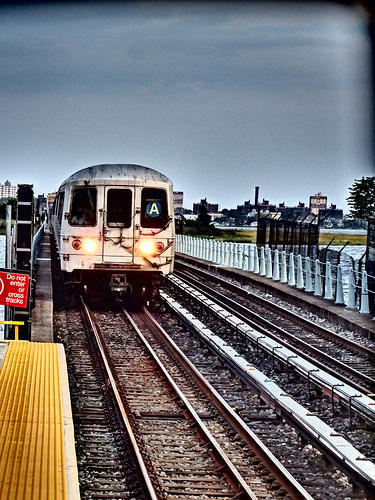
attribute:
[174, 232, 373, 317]
fence — white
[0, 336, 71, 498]
grate — yellow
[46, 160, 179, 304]
train — white, dirty